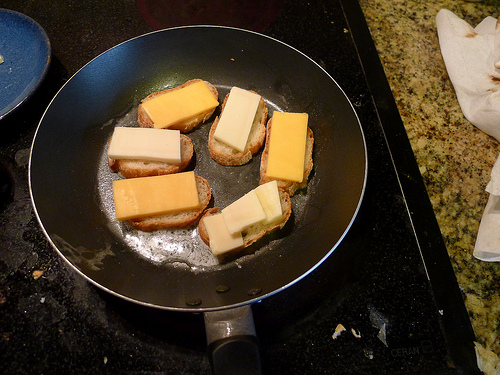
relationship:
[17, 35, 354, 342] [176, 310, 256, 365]
pan has handle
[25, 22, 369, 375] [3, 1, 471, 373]
pan on stove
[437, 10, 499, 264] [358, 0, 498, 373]
towel on counter